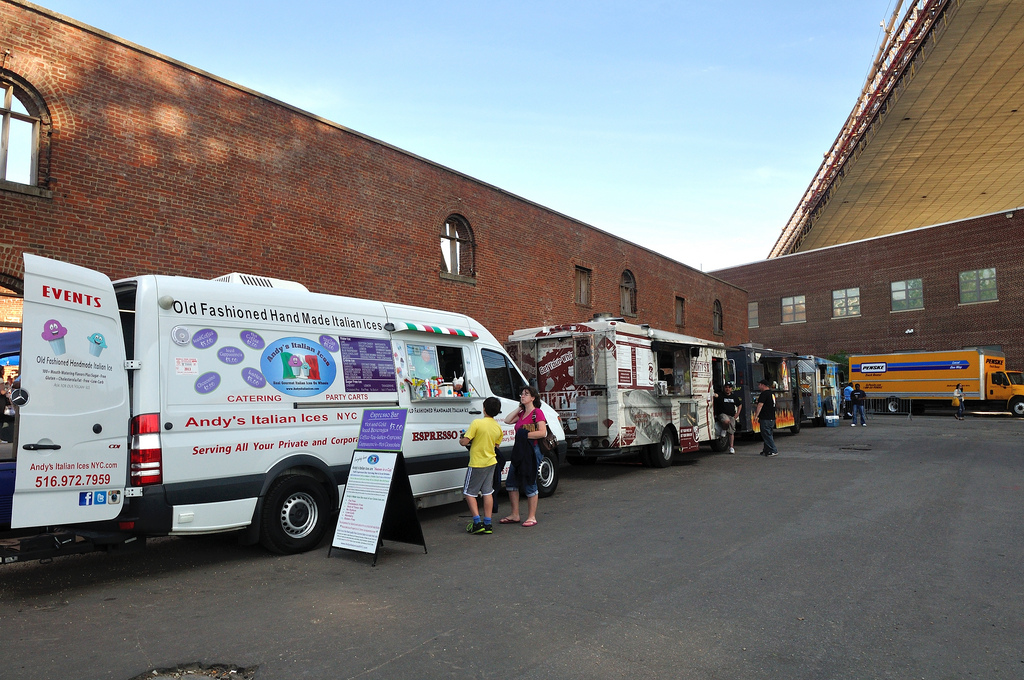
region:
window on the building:
[816, 279, 873, 328]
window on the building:
[883, 278, 922, 316]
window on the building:
[563, 258, 601, 332]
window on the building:
[678, 297, 692, 326]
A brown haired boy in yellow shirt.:
[457, 396, 503, 532]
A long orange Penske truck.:
[845, 346, 1022, 414]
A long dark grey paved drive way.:
[1, 409, 1022, 678]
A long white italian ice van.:
[11, 248, 565, 543]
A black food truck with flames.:
[715, 340, 805, 438]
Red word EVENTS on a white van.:
[38, 283, 102, 310]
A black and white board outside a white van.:
[329, 446, 432, 570]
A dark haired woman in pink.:
[498, 383, 550, 527]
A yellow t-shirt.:
[462, 413, 504, 470]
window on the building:
[892, 277, 938, 315]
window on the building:
[829, 284, 867, 316]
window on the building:
[746, 297, 766, 332]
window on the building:
[706, 285, 732, 342]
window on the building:
[664, 281, 694, 330]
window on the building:
[569, 258, 609, 315]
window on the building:
[416, 205, 493, 301]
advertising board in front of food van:
[321, 400, 433, 565]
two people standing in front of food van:
[463, 384, 552, 528]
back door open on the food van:
[0, 248, 140, 533]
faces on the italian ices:
[38, 312, 112, 368]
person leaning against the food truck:
[707, 382, 746, 454]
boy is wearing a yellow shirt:
[459, 415, 506, 468]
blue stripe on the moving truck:
[845, 358, 970, 376]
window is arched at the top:
[430, 205, 482, 288]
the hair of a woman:
[518, 382, 548, 398]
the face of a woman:
[519, 388, 530, 405]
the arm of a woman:
[519, 405, 554, 443]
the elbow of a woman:
[535, 432, 565, 452]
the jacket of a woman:
[493, 433, 548, 491]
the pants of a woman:
[487, 455, 533, 503]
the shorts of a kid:
[452, 455, 506, 503]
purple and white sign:
[314, 379, 444, 569]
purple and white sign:
[314, 370, 445, 570]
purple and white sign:
[305, 389, 443, 570]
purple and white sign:
[323, 388, 444, 573]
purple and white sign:
[311, 392, 439, 580]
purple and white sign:
[318, 379, 439, 580]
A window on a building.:
[575, 266, 598, 302]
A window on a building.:
[619, 269, 640, 315]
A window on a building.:
[672, 295, 691, 324]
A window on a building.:
[710, 296, 739, 334]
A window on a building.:
[9, 77, 58, 196]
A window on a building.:
[777, 286, 816, 318]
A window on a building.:
[890, 272, 928, 312]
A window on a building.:
[958, 264, 997, 297]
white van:
[26, 228, 549, 557]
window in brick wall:
[431, 209, 483, 276]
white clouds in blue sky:
[653, 217, 730, 257]